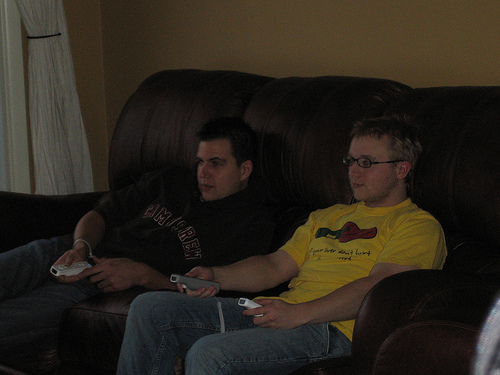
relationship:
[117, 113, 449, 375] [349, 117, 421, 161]
guy has hair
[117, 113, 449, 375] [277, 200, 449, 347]
guy wearing shirt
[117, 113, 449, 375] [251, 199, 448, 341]
guy wearing yellow shirt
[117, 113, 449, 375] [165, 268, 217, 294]
guy holding game controller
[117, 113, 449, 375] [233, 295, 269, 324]
guy holding game controller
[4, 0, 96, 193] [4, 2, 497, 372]
curtain in room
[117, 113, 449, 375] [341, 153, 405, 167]
guy wearing glasses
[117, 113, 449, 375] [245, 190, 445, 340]
guy wearing yellow shirt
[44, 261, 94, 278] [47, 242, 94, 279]
wii control in hand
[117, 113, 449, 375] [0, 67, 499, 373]
guy sitting on couch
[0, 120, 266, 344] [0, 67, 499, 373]
guy sitting on couch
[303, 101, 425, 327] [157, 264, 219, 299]
guy playing with wii remote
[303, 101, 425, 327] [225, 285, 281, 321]
guy playing with wii remote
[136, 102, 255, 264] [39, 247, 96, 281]
guy playing with wii remote